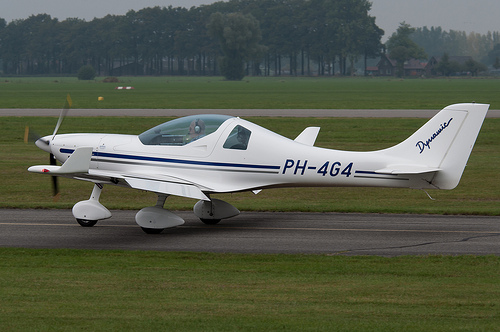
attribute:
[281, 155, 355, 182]
number — identification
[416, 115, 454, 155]
text — black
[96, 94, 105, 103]
object — yellow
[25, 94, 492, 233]
plane — white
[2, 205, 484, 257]
runway — gray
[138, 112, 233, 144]
window — clear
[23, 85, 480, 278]
airplane — white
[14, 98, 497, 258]
plane — 2 passenger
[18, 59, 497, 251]
plane — small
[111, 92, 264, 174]
cockpit — glass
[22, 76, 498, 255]
plane — white, small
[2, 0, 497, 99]
trees — thick, green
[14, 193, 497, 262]
runway — concrete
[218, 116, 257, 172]
window — small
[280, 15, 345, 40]
leaves — green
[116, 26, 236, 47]
leaves — green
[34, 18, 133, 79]
leaves — green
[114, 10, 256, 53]
leaves — green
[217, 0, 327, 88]
leaves — green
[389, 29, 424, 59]
leaves — green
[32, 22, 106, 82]
leaves — green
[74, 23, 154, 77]
leaves — green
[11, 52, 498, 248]
airplane — small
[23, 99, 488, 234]
airplane — white , large 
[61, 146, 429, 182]
stripes — Blue and silver